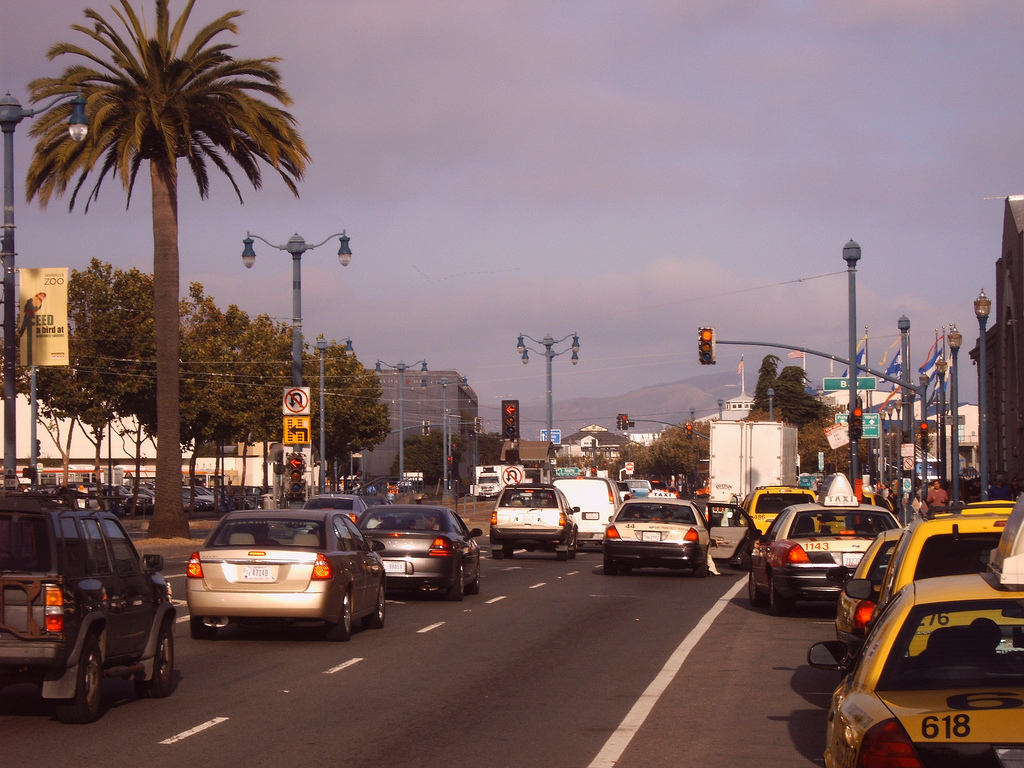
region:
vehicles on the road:
[482, 473, 751, 572]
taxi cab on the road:
[814, 557, 1020, 766]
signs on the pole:
[276, 389, 312, 448]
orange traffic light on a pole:
[694, 318, 737, 369]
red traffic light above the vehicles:
[500, 394, 521, 442]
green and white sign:
[547, 462, 587, 482]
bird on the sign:
[21, 265, 67, 364]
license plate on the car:
[219, 560, 286, 590]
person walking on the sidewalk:
[921, 473, 951, 519]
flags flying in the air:
[915, 332, 953, 391]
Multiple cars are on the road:
[10, 470, 1022, 758]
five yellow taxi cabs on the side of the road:
[718, 470, 1017, 750]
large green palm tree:
[21, 0, 332, 573]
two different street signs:
[269, 375, 333, 465]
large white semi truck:
[699, 408, 807, 536]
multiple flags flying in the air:
[773, 318, 979, 404]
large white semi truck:
[465, 446, 535, 511]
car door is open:
[695, 490, 784, 585]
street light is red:
[489, 395, 527, 443]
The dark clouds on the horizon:
[7, 1, 1022, 376]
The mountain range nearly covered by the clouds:
[477, 357, 855, 430]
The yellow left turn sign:
[275, 409, 318, 457]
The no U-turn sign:
[277, 380, 319, 415]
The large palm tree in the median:
[15, 0, 313, 539]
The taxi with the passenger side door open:
[594, 477, 760, 576]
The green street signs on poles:
[814, 367, 892, 444]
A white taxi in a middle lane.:
[601, 491, 713, 572]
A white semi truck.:
[705, 418, 801, 517]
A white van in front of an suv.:
[548, 478, 624, 552]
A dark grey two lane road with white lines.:
[0, 535, 757, 766]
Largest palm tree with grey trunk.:
[24, 5, 312, 540]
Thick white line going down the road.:
[588, 568, 750, 765]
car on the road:
[0, 525, 144, 703]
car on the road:
[380, 499, 470, 588]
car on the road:
[478, 483, 580, 554]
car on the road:
[590, 495, 723, 575]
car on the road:
[452, 454, 545, 508]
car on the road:
[190, 474, 226, 513]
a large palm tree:
[29, 1, 301, 532]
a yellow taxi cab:
[829, 580, 1019, 755]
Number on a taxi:
[920, 713, 975, 740]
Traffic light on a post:
[680, 323, 722, 371]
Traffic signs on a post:
[275, 378, 314, 452]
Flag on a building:
[726, 343, 750, 394]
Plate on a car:
[230, 560, 284, 586]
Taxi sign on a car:
[814, 473, 875, 508]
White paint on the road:
[525, 576, 548, 596]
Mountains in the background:
[559, 362, 740, 429]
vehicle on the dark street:
[1, 475, 183, 725]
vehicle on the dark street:
[181, 501, 385, 645]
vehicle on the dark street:
[354, 498, 484, 604]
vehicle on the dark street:
[482, 475, 569, 556]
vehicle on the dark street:
[599, 494, 708, 580]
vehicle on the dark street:
[544, 473, 617, 549]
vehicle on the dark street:
[759, 494, 897, 613]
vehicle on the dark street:
[728, 469, 821, 571]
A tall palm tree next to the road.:
[36, 3, 259, 507]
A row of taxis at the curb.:
[759, 482, 1017, 748]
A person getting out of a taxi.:
[687, 497, 754, 575]